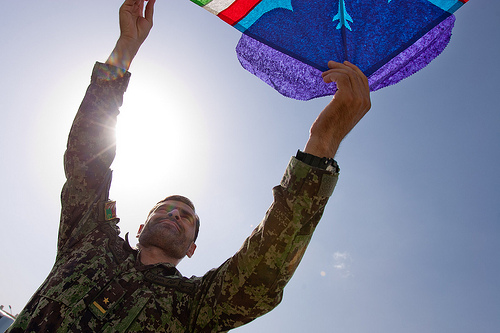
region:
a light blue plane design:
[332, 0, 353, 32]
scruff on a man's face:
[141, 212, 190, 262]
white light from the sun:
[45, 95, 210, 199]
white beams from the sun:
[92, 99, 120, 156]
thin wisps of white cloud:
[318, 243, 360, 293]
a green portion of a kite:
[195, 0, 208, 7]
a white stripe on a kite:
[208, 0, 233, 10]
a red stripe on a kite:
[217, 0, 259, 24]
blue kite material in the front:
[235, 19, 456, 99]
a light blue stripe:
[431, 0, 462, 12]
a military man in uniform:
[64, 9, 342, 324]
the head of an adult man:
[121, 191, 205, 266]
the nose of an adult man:
[155, 208, 185, 220]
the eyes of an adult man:
[151, 198, 196, 220]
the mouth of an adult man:
[152, 209, 177, 234]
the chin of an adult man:
[137, 209, 179, 249]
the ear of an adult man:
[181, 226, 208, 270]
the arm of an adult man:
[65, 18, 150, 166]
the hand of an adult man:
[317, 52, 371, 159]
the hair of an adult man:
[157, 196, 198, 208]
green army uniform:
[3, 53, 348, 331]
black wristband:
[287, 139, 341, 174]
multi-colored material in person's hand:
[176, 0, 480, 110]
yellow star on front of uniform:
[96, 290, 116, 307]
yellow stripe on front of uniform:
[86, 296, 109, 319]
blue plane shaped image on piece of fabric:
[326, 2, 362, 35]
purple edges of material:
[222, 8, 474, 109]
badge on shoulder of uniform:
[97, 193, 122, 231]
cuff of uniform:
[276, 148, 346, 205]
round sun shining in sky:
[35, 73, 198, 195]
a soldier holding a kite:
[85, 1, 446, 327]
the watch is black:
[271, 125, 353, 196]